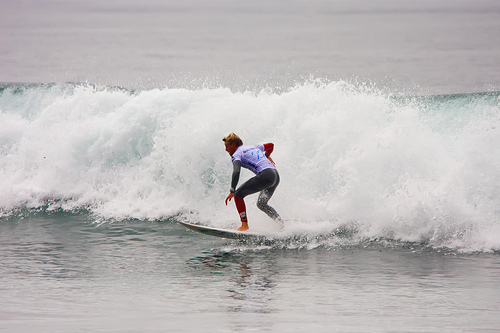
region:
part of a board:
[279, 240, 282, 248]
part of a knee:
[232, 197, 235, 207]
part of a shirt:
[263, 161, 277, 173]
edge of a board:
[196, 190, 207, 221]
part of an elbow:
[234, 180, 239, 195]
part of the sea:
[148, 54, 153, 61]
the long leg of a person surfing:
[229, 170, 272, 225]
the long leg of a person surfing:
[257, 188, 283, 225]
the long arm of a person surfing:
[225, 153, 240, 201]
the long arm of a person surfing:
[253, 143, 274, 161]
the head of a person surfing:
[224, 131, 241, 152]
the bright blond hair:
[222, 132, 243, 144]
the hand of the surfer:
[225, 188, 235, 204]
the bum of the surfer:
[255, 167, 280, 187]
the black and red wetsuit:
[230, 141, 280, 220]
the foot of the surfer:
[234, 220, 249, 232]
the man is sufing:
[181, 115, 331, 243]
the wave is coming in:
[315, 120, 380, 198]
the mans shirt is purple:
[208, 130, 335, 198]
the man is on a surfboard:
[111, 140, 346, 276]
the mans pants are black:
[193, 162, 283, 240]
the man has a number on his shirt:
[203, 115, 298, 209]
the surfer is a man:
[153, 120, 318, 245]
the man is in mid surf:
[149, 120, 339, 243]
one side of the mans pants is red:
[186, 183, 271, 250]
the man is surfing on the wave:
[111, 70, 368, 256]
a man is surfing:
[43, 104, 397, 281]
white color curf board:
[181, 213, 313, 238]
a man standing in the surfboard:
[221, 128, 293, 246]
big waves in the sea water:
[308, 78, 478, 257]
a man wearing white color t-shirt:
[239, 144, 274, 174]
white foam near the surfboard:
[23, 97, 173, 207]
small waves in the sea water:
[244, 17, 458, 85]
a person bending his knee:
[227, 177, 262, 207]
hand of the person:
[223, 173, 233, 205]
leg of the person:
[232, 200, 254, 237]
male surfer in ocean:
[197, 125, 282, 244]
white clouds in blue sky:
[25, 16, 62, 55]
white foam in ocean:
[70, 103, 164, 213]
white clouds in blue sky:
[130, 23, 184, 64]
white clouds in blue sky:
[343, 27, 389, 88]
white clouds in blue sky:
[438, 18, 475, 68]